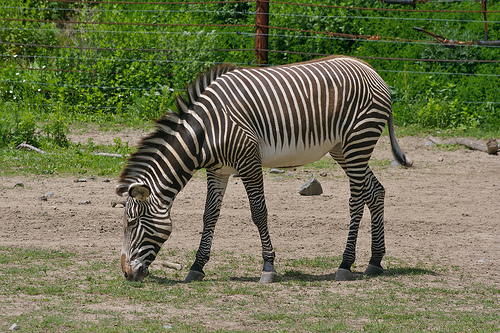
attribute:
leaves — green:
[252, 0, 387, 60]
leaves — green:
[281, 0, 431, 64]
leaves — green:
[121, 17, 241, 63]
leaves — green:
[71, 16, 191, 76]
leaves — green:
[1, 6, 156, 78]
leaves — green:
[418, 75, 465, 118]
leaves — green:
[367, 53, 413, 72]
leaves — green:
[404, 40, 441, 124]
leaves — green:
[409, 40, 467, 128]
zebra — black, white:
[85, 51, 432, 283]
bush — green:
[1, 1, 499, 171]